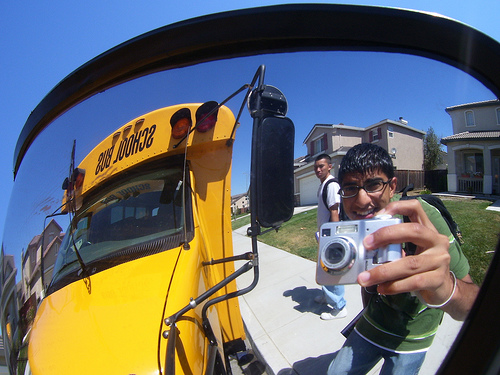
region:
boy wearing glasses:
[330, 143, 397, 215]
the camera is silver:
[310, 216, 407, 287]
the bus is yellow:
[15, 99, 250, 374]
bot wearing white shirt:
[311, 150, 348, 319]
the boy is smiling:
[328, 143, 399, 221]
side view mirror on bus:
[156, 63, 299, 339]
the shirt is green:
[341, 196, 470, 356]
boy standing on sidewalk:
[230, 225, 470, 373]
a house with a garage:
[286, 113, 429, 208]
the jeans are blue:
[323, 326, 426, 373]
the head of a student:
[332, 142, 387, 219]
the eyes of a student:
[340, 181, 390, 193]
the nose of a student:
[352, 183, 382, 210]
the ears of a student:
[382, 178, 399, 195]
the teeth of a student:
[344, 205, 378, 216]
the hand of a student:
[374, 208, 456, 305]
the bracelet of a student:
[415, 266, 457, 313]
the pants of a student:
[328, 309, 413, 373]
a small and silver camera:
[320, 201, 400, 293]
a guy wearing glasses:
[330, 146, 400, 219]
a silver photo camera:
[305, 217, 405, 287]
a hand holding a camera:
[307, 208, 450, 303]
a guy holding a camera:
[305, 140, 454, 302]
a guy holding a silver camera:
[314, 143, 466, 323]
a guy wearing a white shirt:
[308, 150, 337, 201]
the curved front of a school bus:
[70, 122, 172, 174]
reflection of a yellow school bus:
[33, 125, 245, 374]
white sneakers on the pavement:
[308, 291, 353, 323]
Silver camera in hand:
[314, 216, 413, 286]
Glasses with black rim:
[337, 179, 394, 197]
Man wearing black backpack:
[328, 143, 479, 374]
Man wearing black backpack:
[313, 153, 346, 317]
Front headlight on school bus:
[167, 107, 193, 138]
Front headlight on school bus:
[62, 177, 71, 190]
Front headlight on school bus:
[195, 102, 217, 134]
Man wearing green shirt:
[329, 144, 479, 371]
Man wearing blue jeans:
[328, 143, 478, 372]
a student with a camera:
[301, 146, 459, 356]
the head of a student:
[345, 149, 396, 220]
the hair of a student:
[335, 142, 373, 172]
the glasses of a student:
[335, 183, 407, 193]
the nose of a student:
[345, 191, 376, 205]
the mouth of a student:
[354, 206, 385, 214]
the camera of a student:
[300, 229, 394, 289]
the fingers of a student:
[352, 221, 436, 288]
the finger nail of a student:
[351, 269, 368, 287]